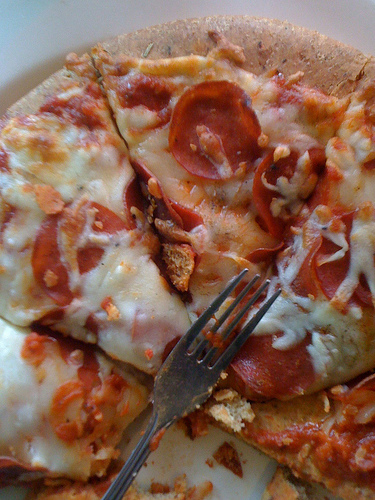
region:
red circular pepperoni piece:
[165, 78, 263, 183]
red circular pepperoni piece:
[259, 148, 301, 234]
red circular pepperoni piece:
[313, 207, 374, 316]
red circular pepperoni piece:
[227, 292, 317, 403]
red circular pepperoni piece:
[31, 197, 123, 303]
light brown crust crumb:
[31, 183, 65, 216]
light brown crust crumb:
[43, 268, 58, 286]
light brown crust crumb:
[105, 304, 120, 324]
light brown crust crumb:
[93, 220, 105, 229]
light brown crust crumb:
[172, 474, 189, 491]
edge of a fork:
[146, 425, 155, 444]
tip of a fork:
[214, 327, 218, 336]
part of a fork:
[165, 390, 170, 399]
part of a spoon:
[190, 392, 195, 398]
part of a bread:
[260, 381, 272, 399]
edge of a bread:
[118, 418, 128, 435]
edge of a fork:
[159, 365, 169, 386]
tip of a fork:
[242, 308, 245, 324]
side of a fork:
[212, 295, 218, 308]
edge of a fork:
[227, 342, 237, 368]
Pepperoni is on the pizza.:
[167, 80, 262, 181]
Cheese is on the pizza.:
[90, 269, 156, 337]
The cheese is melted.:
[92, 261, 154, 305]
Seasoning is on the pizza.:
[139, 42, 155, 58]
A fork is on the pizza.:
[99, 268, 280, 499]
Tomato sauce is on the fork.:
[200, 331, 224, 349]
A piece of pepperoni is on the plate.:
[213, 441, 242, 476]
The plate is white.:
[218, 477, 250, 498]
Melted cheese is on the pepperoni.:
[253, 145, 321, 232]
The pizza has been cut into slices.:
[1, 15, 372, 268]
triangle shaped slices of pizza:
[52, 11, 358, 346]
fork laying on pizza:
[126, 266, 291, 499]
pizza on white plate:
[12, 32, 324, 496]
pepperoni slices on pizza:
[129, 58, 324, 273]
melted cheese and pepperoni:
[20, 192, 221, 382]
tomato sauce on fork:
[161, 295, 256, 413]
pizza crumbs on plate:
[100, 426, 265, 497]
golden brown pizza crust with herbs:
[105, 9, 346, 123]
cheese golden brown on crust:
[91, 38, 347, 136]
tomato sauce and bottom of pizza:
[204, 377, 372, 494]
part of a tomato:
[201, 106, 219, 142]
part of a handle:
[130, 445, 158, 483]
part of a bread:
[224, 396, 252, 439]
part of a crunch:
[210, 428, 229, 490]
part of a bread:
[243, 402, 268, 421]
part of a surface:
[224, 472, 239, 493]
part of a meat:
[249, 348, 262, 368]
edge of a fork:
[155, 419, 171, 448]